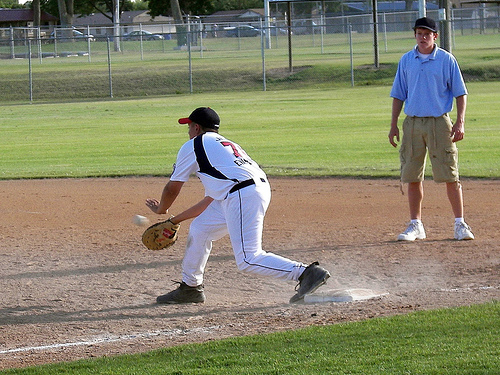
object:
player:
[144, 106, 330, 302]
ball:
[134, 212, 151, 227]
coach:
[388, 16, 477, 243]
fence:
[222, 22, 298, 85]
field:
[64, 112, 124, 162]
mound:
[300, 282, 387, 309]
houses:
[80, 10, 179, 37]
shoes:
[287, 264, 325, 305]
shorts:
[396, 116, 463, 183]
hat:
[406, 14, 438, 32]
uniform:
[171, 132, 307, 286]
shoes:
[394, 224, 426, 244]